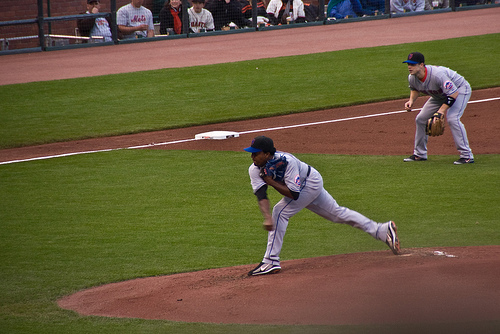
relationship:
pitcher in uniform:
[230, 131, 408, 277] [249, 150, 389, 264]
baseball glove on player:
[423, 115, 446, 138] [403, 51, 475, 164]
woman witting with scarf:
[148, 0, 201, 51] [163, 7, 184, 39]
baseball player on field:
[388, 53, 468, 173] [27, 35, 449, 299]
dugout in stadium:
[17, 13, 467, 50] [12, 11, 462, 67]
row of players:
[21, 3, 466, 52] [67, 6, 438, 42]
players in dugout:
[67, 6, 438, 42] [12, 10, 466, 94]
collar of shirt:
[410, 69, 435, 85] [384, 58, 493, 110]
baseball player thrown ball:
[246, 134, 398, 276] [7, 203, 27, 261]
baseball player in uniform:
[228, 126, 415, 296] [243, 162, 310, 198]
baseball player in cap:
[228, 126, 415, 296] [245, 140, 277, 159]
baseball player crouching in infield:
[400, 50, 475, 163] [99, 142, 482, 231]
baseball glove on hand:
[412, 112, 453, 137] [409, 107, 438, 140]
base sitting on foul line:
[192, 131, 242, 140] [0, 97, 499, 166]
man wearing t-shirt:
[111, 2, 158, 42] [118, 16, 151, 34]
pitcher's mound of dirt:
[100, 251, 475, 320] [165, 271, 442, 308]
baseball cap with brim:
[235, 131, 283, 165] [239, 147, 260, 161]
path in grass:
[2, 88, 484, 170] [2, 31, 484, 146]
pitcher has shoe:
[230, 131, 408, 277] [382, 214, 404, 259]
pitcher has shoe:
[230, 131, 408, 277] [244, 256, 289, 285]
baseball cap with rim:
[244, 137, 275, 152] [241, 146, 261, 156]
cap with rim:
[396, 46, 427, 68] [399, 58, 419, 65]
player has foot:
[400, 46, 477, 167] [451, 155, 478, 167]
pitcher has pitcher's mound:
[240, 135, 403, 276] [53, 245, 499, 326]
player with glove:
[400, 46, 477, 167] [422, 111, 449, 139]